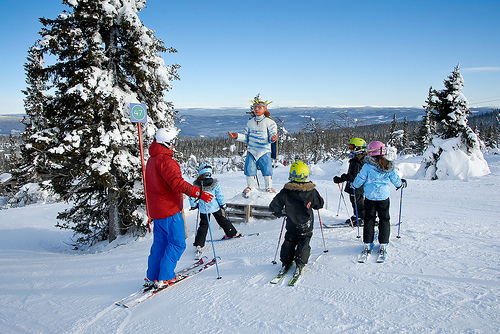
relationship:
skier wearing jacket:
[136, 125, 213, 286] [136, 145, 209, 218]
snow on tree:
[110, 133, 120, 143] [25, 3, 150, 243]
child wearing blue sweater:
[347, 140, 406, 258] [352, 162, 400, 200]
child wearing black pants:
[265, 155, 325, 278] [280, 228, 310, 270]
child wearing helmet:
[265, 155, 325, 278] [288, 161, 309, 181]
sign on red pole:
[128, 100, 145, 122] [133, 121, 152, 230]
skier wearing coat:
[136, 125, 213, 288] [137, 143, 209, 222]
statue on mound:
[223, 94, 285, 199] [0, 143, 497, 331]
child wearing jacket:
[347, 140, 406, 258] [334, 146, 455, 263]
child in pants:
[347, 140, 406, 258] [362, 197, 388, 242]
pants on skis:
[362, 197, 388, 242] [356, 242, 386, 264]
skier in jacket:
[136, 125, 213, 288] [135, 140, 204, 220]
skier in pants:
[136, 125, 213, 288] [141, 213, 186, 280]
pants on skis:
[141, 213, 186, 280] [114, 255, 218, 310]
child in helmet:
[271, 182, 318, 278] [286, 146, 309, 179]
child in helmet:
[347, 154, 406, 263] [340, 136, 362, 157]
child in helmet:
[336, 146, 367, 225] [361, 139, 384, 165]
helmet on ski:
[286, 146, 309, 179] [314, 206, 332, 259]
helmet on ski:
[340, 136, 362, 157] [394, 173, 406, 242]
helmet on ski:
[361, 139, 384, 165] [271, 208, 287, 270]